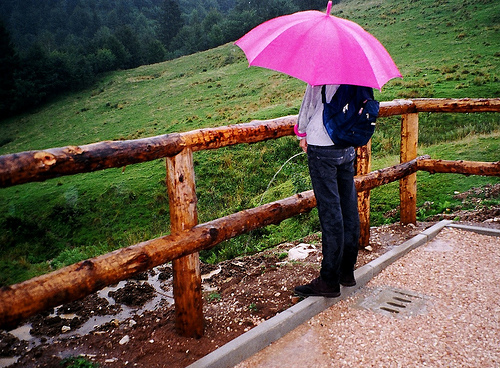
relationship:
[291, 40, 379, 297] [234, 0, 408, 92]
man has an open umbrella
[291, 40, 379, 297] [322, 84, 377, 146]
man has a backpack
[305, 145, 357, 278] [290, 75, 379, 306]
denim jeans are on man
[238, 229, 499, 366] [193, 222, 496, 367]
gravel surrounded by curb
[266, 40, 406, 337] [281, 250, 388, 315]
man has shoes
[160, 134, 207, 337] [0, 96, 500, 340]
post painted fence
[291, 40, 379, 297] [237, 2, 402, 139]
man holding umbrella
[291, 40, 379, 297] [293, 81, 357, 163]
man wearing shirt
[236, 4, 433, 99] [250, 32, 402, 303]
umbrella covering person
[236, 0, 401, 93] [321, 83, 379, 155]
umbrella covering backpack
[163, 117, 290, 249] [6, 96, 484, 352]
fence around overlook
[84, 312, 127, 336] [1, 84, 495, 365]
ice around overlook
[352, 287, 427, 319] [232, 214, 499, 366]
drain in gravel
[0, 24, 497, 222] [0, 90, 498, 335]
grass behind fence